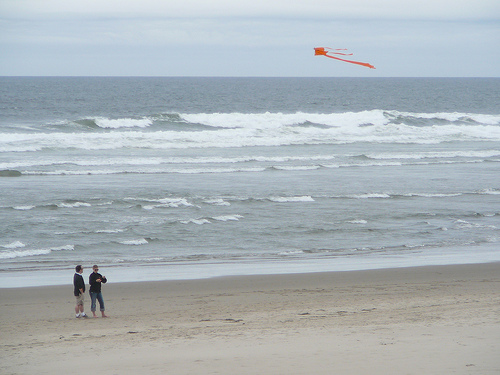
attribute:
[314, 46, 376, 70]
kite — is orange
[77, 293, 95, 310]
shorts — are khaki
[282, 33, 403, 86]
kite — orange 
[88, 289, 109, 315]
capris — are blue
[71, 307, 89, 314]
socks — are white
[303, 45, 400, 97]
kite — is red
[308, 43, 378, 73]
kite — is orange, in the air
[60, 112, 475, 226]
water — is white, is choppy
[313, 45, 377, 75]
kite — is orange, has tails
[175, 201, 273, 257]
water — body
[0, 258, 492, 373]
sand — is brown, is light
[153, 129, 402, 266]
water — is choppy, has waves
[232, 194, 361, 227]
waves — in water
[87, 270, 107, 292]
sweater — is black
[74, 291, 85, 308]
shorts — cargo 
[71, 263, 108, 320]
couple — casually, dressed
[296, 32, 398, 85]
orange kite — is orange, has a tail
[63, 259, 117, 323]
people — standing together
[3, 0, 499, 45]
cloud — is thick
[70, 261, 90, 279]
hair — dark